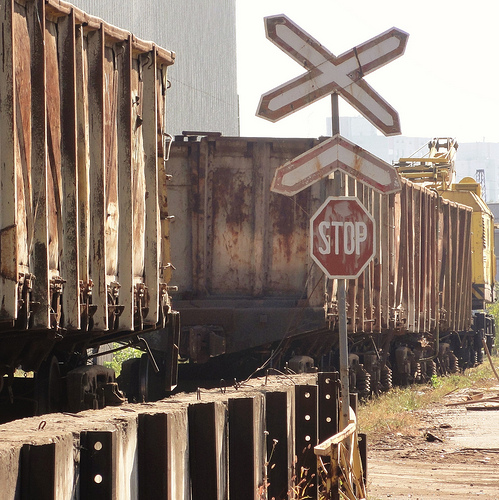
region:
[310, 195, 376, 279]
the stop sign is dirty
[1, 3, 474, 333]
the boxes are rusty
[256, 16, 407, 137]
a sign in the shape of an x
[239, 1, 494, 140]
the sky is white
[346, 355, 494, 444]
the grass is long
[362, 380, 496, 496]
a lot of dust on the ground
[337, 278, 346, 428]
the pole is made of metal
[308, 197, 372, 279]
the sign is red and white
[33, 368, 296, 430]
metal wires sticking out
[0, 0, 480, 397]
the train is dirty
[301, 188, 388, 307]
Stop sign is red and white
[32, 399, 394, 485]
Metal lining the side of the road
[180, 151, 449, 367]
Rusty back of a truck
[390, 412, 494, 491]
The pavement is crumbling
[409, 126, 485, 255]
Yellow machine behind the trailer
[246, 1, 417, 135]
Cross that is red and white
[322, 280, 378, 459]
Pole underneath the stop sign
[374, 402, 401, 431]
Short and green grass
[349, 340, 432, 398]
Rusty wheels under trailer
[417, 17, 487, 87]
The sky is cloudy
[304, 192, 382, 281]
a red stop sign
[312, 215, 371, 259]
white letters on the sign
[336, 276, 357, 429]
a metal sign post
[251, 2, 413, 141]
a train crossing sign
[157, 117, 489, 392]
a metal train car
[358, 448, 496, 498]
a small dirt road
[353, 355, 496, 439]
a patch of grass and weeds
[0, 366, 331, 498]
a small cement wall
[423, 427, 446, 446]
a rock on the ground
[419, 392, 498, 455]
asphalt on the ground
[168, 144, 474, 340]
a rusty freight container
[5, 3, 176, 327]
a rusty freight container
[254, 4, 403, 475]
a railway crossing sign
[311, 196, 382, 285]
a sign that says stop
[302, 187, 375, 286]
a red sign on the crossing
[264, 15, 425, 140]
a cross railway sign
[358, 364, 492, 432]
a patch of grass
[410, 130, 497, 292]
the front is yellow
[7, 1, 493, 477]
this is a train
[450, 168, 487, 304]
the head of a train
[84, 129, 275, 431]
the container is old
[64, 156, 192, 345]
the container is old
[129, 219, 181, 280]
the container is old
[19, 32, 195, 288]
the container is old